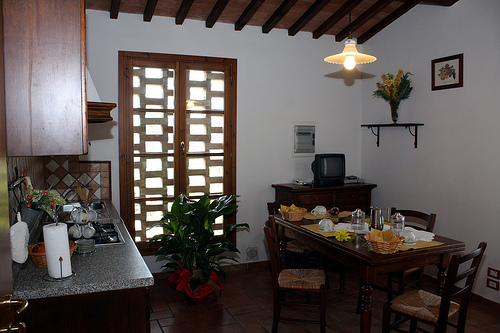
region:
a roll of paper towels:
[43, 217, 83, 284]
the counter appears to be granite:
[29, 250, 141, 285]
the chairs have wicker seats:
[255, 216, 338, 320]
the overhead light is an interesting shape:
[319, 11, 392, 92]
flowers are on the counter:
[24, 177, 69, 237]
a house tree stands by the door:
[146, 159, 255, 308]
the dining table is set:
[256, 196, 459, 287]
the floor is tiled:
[176, 310, 294, 325]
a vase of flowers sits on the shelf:
[377, 55, 429, 132]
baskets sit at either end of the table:
[276, 197, 409, 272]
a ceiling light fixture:
[322, 0, 380, 73]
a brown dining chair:
[259, 215, 334, 330]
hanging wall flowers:
[373, 70, 413, 125]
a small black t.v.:
[309, 151, 350, 181]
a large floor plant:
[147, 170, 251, 300]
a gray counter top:
[1, 242, 156, 297]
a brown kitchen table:
[270, 205, 469, 331]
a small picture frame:
[426, 52, 466, 89]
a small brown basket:
[362, 228, 403, 255]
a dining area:
[144, 70, 489, 328]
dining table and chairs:
[260, 187, 490, 330]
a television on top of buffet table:
[308, 146, 350, 186]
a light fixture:
[321, 32, 379, 88]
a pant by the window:
[153, 175, 248, 315]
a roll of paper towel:
[37, 214, 82, 289]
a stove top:
[53, 206, 123, 261]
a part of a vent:
[83, 52, 117, 134]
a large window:
[117, 47, 244, 249]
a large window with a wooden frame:
[111, 44, 253, 267]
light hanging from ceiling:
[270, 9, 415, 93]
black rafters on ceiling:
[224, 9, 416, 42]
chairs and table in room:
[272, 193, 437, 330]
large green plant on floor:
[144, 182, 259, 302]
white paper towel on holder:
[36, 214, 84, 291]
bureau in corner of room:
[267, 144, 409, 233]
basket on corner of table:
[350, 210, 424, 270]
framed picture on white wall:
[422, 38, 491, 116]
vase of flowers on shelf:
[371, 71, 433, 162]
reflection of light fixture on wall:
[315, 56, 405, 93]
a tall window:
[104, 16, 281, 282]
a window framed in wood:
[116, 45, 255, 261]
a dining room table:
[220, 162, 483, 329]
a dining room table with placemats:
[271, 167, 470, 323]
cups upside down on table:
[288, 162, 460, 319]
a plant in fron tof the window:
[107, 43, 261, 308]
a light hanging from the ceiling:
[318, 3, 381, 92]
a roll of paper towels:
[19, 197, 113, 311]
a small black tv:
[298, 144, 353, 186]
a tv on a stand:
[265, 138, 390, 233]